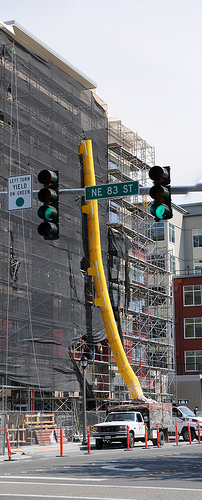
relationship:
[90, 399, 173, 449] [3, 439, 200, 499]
truck on street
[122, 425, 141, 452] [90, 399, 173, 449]
wheel on truck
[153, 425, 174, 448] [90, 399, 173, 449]
tire on truck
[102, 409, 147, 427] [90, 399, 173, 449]
windshield on truck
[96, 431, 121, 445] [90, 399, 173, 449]
license plate on truck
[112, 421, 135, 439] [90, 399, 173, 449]
headlight on truck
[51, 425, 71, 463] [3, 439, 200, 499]
traffic post on street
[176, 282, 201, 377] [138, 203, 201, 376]
windows are on building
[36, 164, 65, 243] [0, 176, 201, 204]
traffic signal on pole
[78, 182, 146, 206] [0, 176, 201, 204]
street sign on a pole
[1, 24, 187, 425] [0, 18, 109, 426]
building being building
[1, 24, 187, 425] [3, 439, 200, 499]
building by street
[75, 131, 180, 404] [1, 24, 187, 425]
tube by building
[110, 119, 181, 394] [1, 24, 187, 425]
scaffolding on building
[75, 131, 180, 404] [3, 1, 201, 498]
tube at construction site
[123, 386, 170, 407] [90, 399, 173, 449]
garbage in truck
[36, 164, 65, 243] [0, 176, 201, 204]
traffic signal on a pole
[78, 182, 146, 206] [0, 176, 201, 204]
street sign on pole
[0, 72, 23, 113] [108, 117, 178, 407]
person on scaffolding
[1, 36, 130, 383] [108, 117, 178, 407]
mesh on scaffolding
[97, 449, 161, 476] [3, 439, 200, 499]
arrow on street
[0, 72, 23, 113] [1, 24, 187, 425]
person on building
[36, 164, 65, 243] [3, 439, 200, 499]
traffic signal over street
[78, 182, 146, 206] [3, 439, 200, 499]
street sign over street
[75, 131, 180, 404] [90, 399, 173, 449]
tube over truck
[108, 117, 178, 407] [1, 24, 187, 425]
scaffolding over building